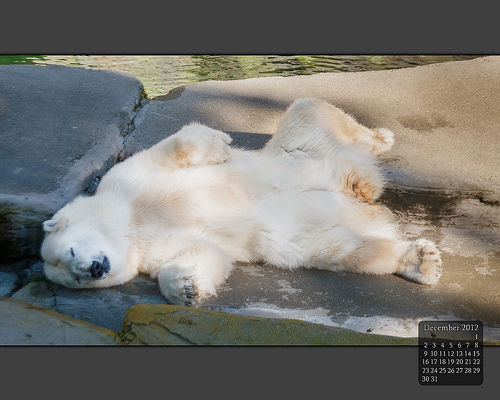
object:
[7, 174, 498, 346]
pavement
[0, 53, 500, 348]
outside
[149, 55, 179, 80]
water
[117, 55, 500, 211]
rock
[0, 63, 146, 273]
rock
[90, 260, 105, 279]
nose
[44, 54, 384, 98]
pool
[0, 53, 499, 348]
scene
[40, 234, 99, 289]
face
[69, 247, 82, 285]
eyes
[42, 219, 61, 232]
ear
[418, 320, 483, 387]
calendar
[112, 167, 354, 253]
fur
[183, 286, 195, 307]
claws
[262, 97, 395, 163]
leg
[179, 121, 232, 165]
paw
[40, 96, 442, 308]
bear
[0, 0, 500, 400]
photo